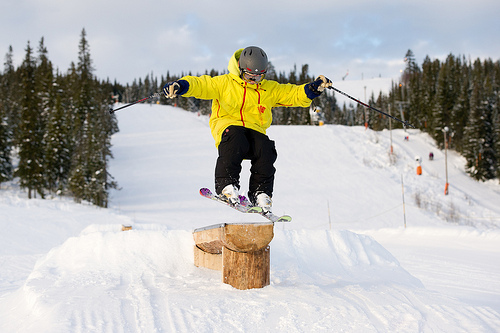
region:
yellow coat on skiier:
[175, 50, 311, 140]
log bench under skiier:
[191, 220, 276, 290]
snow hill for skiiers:
[10, 232, 150, 327]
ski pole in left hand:
[316, 73, 419, 138]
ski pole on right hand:
[70, 81, 165, 127]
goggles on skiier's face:
[244, 70, 267, 80]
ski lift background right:
[350, 87, 498, 247]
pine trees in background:
[3, 28, 120, 211]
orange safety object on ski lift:
[415, 159, 425, 179]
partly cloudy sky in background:
[9, 1, 486, 71]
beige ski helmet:
[231, 43, 278, 78]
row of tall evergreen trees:
[1, 30, 121, 205]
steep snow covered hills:
[294, 118, 412, 332]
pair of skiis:
[193, 171, 303, 226]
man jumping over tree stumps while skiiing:
[103, 34, 426, 293]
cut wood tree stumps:
[176, 218, 286, 290]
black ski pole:
[313, 67, 433, 149]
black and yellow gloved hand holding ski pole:
[95, 78, 190, 114]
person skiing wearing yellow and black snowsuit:
[146, 42, 337, 224]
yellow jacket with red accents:
[177, 72, 313, 138]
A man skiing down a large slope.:
[101, 36, 411, 242]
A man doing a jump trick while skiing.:
[190, 176, 302, 300]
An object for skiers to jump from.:
[186, 213, 288, 280]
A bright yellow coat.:
[180, 62, 313, 127]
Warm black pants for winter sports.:
[202, 120, 300, 187]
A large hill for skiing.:
[105, 91, 475, 312]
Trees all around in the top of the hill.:
[10, 30, 125, 190]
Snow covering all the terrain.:
[106, 92, 482, 322]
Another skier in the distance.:
[410, 151, 448, 167]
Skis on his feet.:
[187, 177, 292, 219]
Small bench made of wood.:
[185, 208, 275, 285]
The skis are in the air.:
[201, 197, 291, 219]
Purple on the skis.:
[177, 178, 234, 208]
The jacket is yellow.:
[218, 93, 245, 117]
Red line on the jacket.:
[233, 97, 270, 120]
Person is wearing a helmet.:
[236, 45, 268, 69]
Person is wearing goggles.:
[234, 67, 278, 87]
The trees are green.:
[417, 91, 454, 117]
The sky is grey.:
[80, 20, 144, 50]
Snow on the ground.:
[84, 281, 144, 317]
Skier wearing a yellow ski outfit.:
[159, 46, 340, 220]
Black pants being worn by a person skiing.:
[198, 131, 287, 197]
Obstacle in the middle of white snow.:
[176, 216, 295, 301]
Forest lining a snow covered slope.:
[0, 37, 115, 210]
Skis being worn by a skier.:
[184, 189, 295, 239]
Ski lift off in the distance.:
[375, 117, 482, 207]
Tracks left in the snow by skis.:
[83, 285, 183, 318]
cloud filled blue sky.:
[0, 5, 489, 57]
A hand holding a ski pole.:
[300, 60, 440, 150]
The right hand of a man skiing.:
[154, 76, 189, 108]